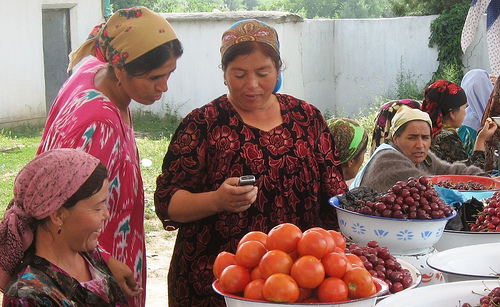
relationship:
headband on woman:
[67, 5, 181, 62] [358, 105, 487, 192]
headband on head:
[422, 80, 467, 135] [423, 79, 467, 109]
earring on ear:
[48, 212, 65, 247] [109, 63, 131, 85]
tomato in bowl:
[265, 220, 300, 254] [209, 224, 386, 304]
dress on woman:
[153, 91, 350, 305] [151, 15, 363, 303]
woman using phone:
[151, 15, 363, 303] [232, 171, 260, 187]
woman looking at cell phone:
[151, 15, 363, 303] [234, 162, 283, 207]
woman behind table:
[0, 147, 127, 304] [348, 222, 485, 291]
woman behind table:
[40, 5, 182, 305] [348, 222, 485, 291]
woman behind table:
[151, 15, 363, 303] [348, 222, 485, 291]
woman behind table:
[327, 117, 367, 179] [348, 222, 485, 291]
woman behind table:
[350, 103, 494, 190] [348, 222, 485, 291]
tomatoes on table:
[215, 201, 363, 305] [312, 200, 452, 298]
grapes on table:
[376, 180, 416, 214] [312, 200, 452, 298]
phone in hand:
[237, 173, 266, 190] [224, 166, 270, 201]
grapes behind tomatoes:
[352, 236, 412, 297] [211, 221, 377, 303]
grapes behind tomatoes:
[358, 172, 456, 219] [211, 221, 377, 303]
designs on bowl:
[336, 217, 352, 229] [328, 190, 455, 256]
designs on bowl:
[347, 219, 367, 236] [328, 190, 455, 256]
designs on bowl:
[372, 226, 396, 236] [328, 190, 455, 256]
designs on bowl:
[394, 227, 414, 241] [328, 190, 455, 256]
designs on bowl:
[418, 229, 432, 242] [328, 190, 455, 256]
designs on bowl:
[433, 225, 445, 240] [328, 190, 455, 256]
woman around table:
[153, 18, 350, 307] [189, 189, 461, 296]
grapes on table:
[358, 172, 456, 219] [239, 222, 439, 291]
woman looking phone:
[153, 18, 350, 307] [238, 174, 256, 185]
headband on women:
[67, 5, 181, 62] [165, 9, 389, 301]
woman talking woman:
[350, 103, 494, 190] [421, 77, 496, 169]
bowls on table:
[340, 207, 440, 256] [250, 154, 441, 253]